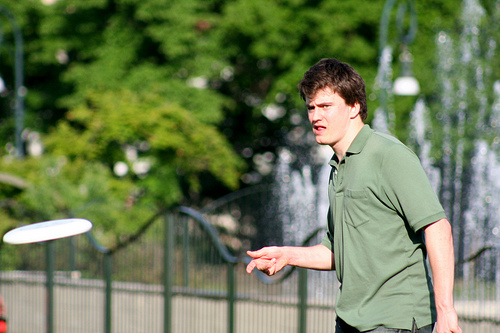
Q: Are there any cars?
A: No, there are no cars.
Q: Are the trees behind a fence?
A: Yes, the trees are behind a fence.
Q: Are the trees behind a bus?
A: No, the trees are behind a fence.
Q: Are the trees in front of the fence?
A: No, the trees are behind the fence.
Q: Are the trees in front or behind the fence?
A: The trees are behind the fence.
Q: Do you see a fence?
A: Yes, there is a fence.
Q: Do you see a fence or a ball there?
A: Yes, there is a fence.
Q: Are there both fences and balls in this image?
A: No, there is a fence but no balls.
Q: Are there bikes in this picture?
A: No, there are no bikes.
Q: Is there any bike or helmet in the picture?
A: No, there are no bikes or helmets.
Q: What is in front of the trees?
A: The fence is in front of the trees.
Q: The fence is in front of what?
A: The fence is in front of the trees.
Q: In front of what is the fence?
A: The fence is in front of the trees.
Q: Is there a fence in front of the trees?
A: Yes, there is a fence in front of the trees.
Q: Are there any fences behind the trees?
A: No, the fence is in front of the trees.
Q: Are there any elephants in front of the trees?
A: No, there is a fence in front of the trees.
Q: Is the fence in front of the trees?
A: Yes, the fence is in front of the trees.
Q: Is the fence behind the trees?
A: No, the fence is in front of the trees.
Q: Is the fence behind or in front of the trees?
A: The fence is in front of the trees.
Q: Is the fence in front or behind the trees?
A: The fence is in front of the trees.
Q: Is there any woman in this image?
A: No, there are no women.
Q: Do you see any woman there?
A: No, there are no women.